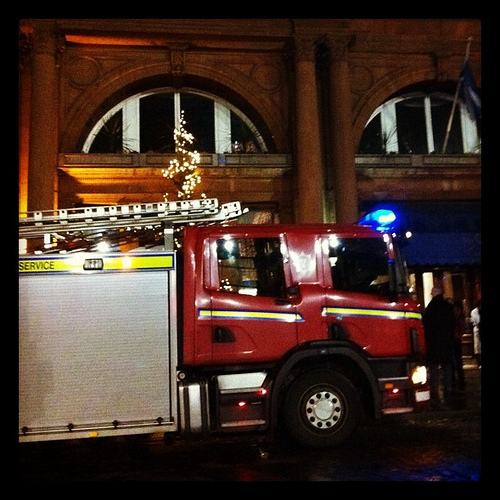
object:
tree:
[160, 109, 204, 201]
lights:
[184, 175, 194, 180]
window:
[218, 237, 290, 295]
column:
[293, 38, 321, 222]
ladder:
[20, 200, 251, 235]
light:
[122, 258, 133, 268]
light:
[373, 207, 398, 223]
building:
[20, 18, 485, 366]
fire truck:
[16, 196, 434, 454]